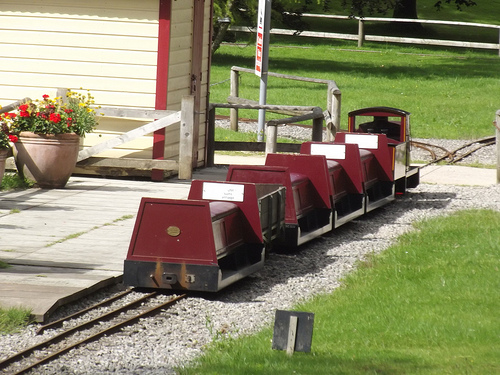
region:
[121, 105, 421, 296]
Small passenger train sitting on tracks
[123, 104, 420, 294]
Mini maroon train sitting on tracks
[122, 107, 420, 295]
Empty small train sitting on tracks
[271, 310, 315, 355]
Small metal sign in the grass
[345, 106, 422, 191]
Engine on front of the train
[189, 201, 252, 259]
Seat inside of the train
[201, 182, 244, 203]
White sign on inside of train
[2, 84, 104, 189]
Yellow and red flowers growing inside of pot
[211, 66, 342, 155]
Wooden fence next to the train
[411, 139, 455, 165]
Rusty track in front of train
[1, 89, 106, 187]
a planter pot with flowers in it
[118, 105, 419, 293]
a small electric train on a rail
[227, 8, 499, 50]
a wooden fence on a lawn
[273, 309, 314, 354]
a metal sign on a wooden post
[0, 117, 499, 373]
a pebble path next to a house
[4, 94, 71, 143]
red flowers in a planter pot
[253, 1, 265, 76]
a sign with black and red writing on it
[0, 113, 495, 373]
a metal train trail on the ground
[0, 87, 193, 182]
a small wooden fence next to a planter pot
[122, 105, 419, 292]
a red and black electric train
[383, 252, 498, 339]
green grass in the yard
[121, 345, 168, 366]
track ballast used for facilitating drainage of water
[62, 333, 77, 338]
railroad ties made from prestressed concrete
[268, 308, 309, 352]
sign on wooden stick coming from grass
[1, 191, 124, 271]
planks of wood used for station platform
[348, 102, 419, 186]
head cart on train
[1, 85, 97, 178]
pot of yellow and red flowers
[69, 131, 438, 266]
small train on a track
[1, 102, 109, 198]
flower in a pot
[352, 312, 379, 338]
patch of green grass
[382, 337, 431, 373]
patch of green grass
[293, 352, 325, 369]
patch of green grass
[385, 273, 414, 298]
patch of green grass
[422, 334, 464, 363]
patch of green grass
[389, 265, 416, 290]
patch of green grass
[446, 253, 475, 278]
patch of green grass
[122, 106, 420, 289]
the sitting train on the track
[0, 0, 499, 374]
the grass around the sitting train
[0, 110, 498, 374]
the tracks on the ground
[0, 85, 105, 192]
the flower planters near the train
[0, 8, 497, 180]
the wooden fence near the train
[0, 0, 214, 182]
the building near the train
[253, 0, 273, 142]
the sign near the train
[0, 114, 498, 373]
the rocks around the tracks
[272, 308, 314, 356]
the back of the sign in the grass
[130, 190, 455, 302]
the shadow from the train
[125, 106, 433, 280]
A small train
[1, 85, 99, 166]
Red and yellow flowers.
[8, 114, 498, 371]
Grey gravel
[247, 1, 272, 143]
Signs on a pole.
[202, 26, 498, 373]
A grassy area.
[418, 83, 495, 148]
grass that is green in color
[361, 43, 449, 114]
the shadow of a big tree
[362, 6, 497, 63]
a fence that is wooden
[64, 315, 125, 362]
tracks that are made of metal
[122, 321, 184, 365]
rocks that are grey in color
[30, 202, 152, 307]
a deck that is made of wood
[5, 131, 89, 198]
a pot that is brown in color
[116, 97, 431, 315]
a toy train in a garden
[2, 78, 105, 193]
the pot has flowers